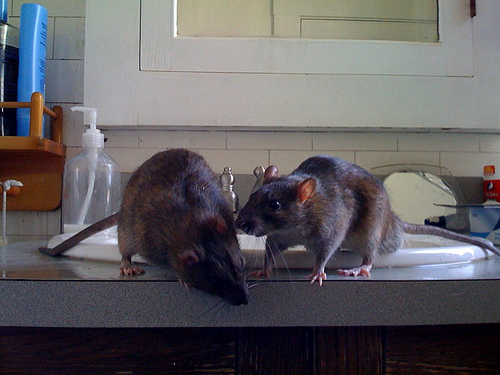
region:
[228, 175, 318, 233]
head of a mouse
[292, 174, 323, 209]
ear of a mouse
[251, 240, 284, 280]
hand of a mouse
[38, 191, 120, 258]
tail of a mouse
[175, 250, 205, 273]
ear of a mouse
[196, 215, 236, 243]
ear of a mouse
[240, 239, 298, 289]
whiskers of a mouse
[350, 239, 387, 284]
leg of a mouse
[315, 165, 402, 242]
body of a mouse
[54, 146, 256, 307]
the mouse is on the sink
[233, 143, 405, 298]
the mouse is on the sink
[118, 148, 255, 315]
the mouse is grey in color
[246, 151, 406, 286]
the mouse is grey in color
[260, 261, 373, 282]
the mouse has pink paws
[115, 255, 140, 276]
the mouse has pink paws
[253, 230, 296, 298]
the mouse has whiskers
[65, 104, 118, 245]
a bottle is on the sink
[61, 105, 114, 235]
the bottle is made of plastic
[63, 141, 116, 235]
the bottle is clear and transparent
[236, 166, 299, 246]
face of the rat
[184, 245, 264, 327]
face of the another rat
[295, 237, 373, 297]
legs of the rate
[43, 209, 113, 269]
tail of the rat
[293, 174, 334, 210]
ear of the rat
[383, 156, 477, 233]
a plate on the back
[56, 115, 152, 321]
a bottle in the back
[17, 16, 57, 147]
a shampoo bottle in back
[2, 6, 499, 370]
Interior, showing animals in human habitat.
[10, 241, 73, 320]
Grey, laminated bathroom counter.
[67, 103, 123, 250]
Clear, squirt bottle with minimal product, obstructed by tail.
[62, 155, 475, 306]
Grey ledge, fronting porcelain, white sink, featuring two rodents.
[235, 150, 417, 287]
Grey mouse, or rat, apparently sniffing second mouse, or rat.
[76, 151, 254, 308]
Large rat-type rodent, with head, stretched over edge of counter.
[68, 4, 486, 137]
Bottom portion of medicine chest with mirror, mounted on tile.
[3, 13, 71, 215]
Mounted shelf, with bottles.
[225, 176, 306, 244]
head of a mice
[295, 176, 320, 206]
ear of a mice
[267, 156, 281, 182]
ear of a mice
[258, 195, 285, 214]
eye of a mice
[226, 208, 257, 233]
nose of a mice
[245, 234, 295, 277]
whisker of a mice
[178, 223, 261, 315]
head of a mice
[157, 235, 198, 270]
ear of a mice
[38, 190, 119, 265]
tail of a mice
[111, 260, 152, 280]
feet of a mice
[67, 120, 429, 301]
two rats on the sink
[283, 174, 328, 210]
ear of the mouse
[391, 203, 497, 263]
tail of the animal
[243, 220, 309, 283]
whiskers on the animals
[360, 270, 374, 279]
toe on rats foot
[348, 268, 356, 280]
toe on rats foot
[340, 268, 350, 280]
toe on rats foot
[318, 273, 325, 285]
toe on rats foot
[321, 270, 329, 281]
toe on rats foot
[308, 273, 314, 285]
toe on rats foot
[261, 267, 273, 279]
toe on rats foot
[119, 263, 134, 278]
toe on rats foot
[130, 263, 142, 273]
toe on rats foot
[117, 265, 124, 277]
toe on rats foot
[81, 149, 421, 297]
Rats on counter top